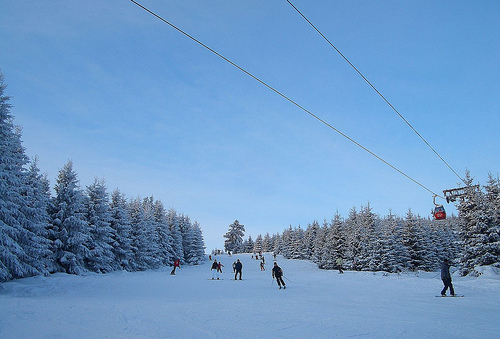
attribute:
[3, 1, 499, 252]
clouds — white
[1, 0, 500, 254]
sky — blue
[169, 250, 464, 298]
people — skiing, going downhill, skiing downhill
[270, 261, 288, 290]
man — skiing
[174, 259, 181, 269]
jacket — red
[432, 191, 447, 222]
ski lift — red